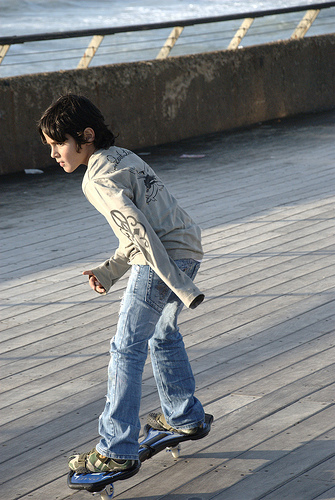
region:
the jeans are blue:
[103, 284, 214, 445]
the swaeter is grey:
[86, 158, 220, 275]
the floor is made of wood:
[237, 326, 314, 480]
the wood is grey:
[244, 365, 319, 419]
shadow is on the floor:
[229, 437, 311, 497]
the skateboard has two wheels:
[79, 411, 230, 498]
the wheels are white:
[101, 439, 210, 498]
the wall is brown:
[112, 62, 266, 131]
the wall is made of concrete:
[181, 53, 281, 130]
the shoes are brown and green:
[58, 445, 137, 480]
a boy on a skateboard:
[35, 93, 212, 495]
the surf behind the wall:
[0, 0, 329, 72]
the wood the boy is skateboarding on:
[0, 112, 331, 493]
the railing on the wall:
[0, 0, 330, 73]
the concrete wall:
[0, 36, 332, 170]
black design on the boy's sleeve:
[106, 207, 145, 245]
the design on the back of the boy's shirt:
[131, 166, 161, 202]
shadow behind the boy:
[112, 438, 330, 494]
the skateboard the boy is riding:
[67, 410, 209, 493]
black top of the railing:
[0, 0, 331, 47]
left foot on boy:
[69, 453, 145, 471]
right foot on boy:
[151, 409, 202, 431]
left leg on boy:
[106, 299, 150, 419]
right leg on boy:
[160, 335, 218, 480]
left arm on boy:
[125, 192, 203, 314]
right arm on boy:
[96, 225, 127, 275]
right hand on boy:
[87, 261, 110, 298]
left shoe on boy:
[72, 445, 184, 493]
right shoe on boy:
[156, 413, 211, 435]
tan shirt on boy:
[91, 175, 207, 277]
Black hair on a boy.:
[32, 93, 117, 148]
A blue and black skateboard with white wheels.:
[66, 411, 213, 498]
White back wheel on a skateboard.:
[167, 444, 181, 459]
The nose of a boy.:
[48, 141, 60, 157]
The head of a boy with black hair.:
[39, 94, 97, 172]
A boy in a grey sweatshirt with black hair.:
[39, 93, 205, 471]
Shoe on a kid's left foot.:
[66, 449, 136, 472]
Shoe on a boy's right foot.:
[147, 410, 205, 436]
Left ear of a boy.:
[82, 127, 95, 143]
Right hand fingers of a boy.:
[83, 269, 107, 294]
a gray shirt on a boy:
[80, 144, 207, 313]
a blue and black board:
[65, 408, 220, 499]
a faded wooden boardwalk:
[0, 107, 333, 498]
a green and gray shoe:
[64, 445, 139, 475]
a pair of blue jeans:
[90, 256, 207, 458]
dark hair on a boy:
[37, 91, 117, 147]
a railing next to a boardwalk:
[0, 1, 333, 77]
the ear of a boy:
[82, 126, 97, 143]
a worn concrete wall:
[1, 34, 332, 179]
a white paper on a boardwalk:
[21, 163, 44, 177]